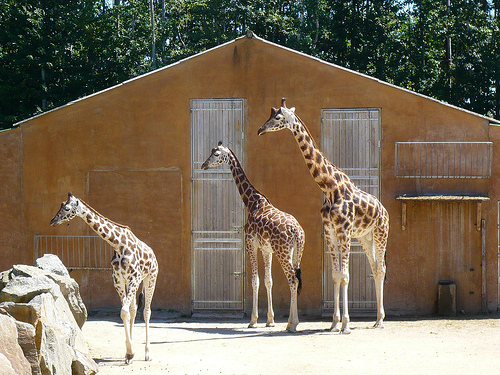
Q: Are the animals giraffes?
A: Yes, all the animals are giraffes.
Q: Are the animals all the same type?
A: Yes, all the animals are giraffes.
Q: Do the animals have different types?
A: No, all the animals are giraffes.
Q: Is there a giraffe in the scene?
A: Yes, there are giraffes.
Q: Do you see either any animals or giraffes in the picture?
A: Yes, there are giraffes.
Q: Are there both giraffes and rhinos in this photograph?
A: No, there are giraffes but no rhinos.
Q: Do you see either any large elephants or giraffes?
A: Yes, there are large giraffes.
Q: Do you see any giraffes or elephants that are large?
A: Yes, the giraffes are large.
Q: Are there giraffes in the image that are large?
A: Yes, there are large giraffes.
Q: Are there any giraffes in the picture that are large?
A: Yes, there are giraffes that are large.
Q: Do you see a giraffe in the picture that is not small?
A: Yes, there are large giraffes.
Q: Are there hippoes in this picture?
A: No, there are no hippoes.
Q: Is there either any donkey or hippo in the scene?
A: No, there are no hippoes or donkeys.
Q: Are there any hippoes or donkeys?
A: No, there are no hippoes or donkeys.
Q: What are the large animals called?
A: The animals are giraffes.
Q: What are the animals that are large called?
A: The animals are giraffes.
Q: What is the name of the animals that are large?
A: The animals are giraffes.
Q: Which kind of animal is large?
A: The animal is giraffes.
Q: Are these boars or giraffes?
A: These are giraffes.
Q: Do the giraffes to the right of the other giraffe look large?
A: Yes, the giraffes are large.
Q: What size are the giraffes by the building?
A: The giraffes are large.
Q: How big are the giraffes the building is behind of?
A: The giraffes are large.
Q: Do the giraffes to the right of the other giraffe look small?
A: No, the giraffes are large.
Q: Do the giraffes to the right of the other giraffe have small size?
A: No, the giraffes are large.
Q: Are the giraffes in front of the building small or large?
A: The giraffes are large.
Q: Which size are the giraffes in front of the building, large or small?
A: The giraffes are large.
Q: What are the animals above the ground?
A: The animals are giraffes.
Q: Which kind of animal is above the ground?
A: The animals are giraffes.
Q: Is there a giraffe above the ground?
A: Yes, there are giraffes above the ground.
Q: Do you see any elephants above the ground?
A: No, there are giraffes above the ground.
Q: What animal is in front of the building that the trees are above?
A: The giraffes are in front of the building.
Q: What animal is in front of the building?
A: The giraffes are in front of the building.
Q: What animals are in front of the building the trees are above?
A: The animals are giraffes.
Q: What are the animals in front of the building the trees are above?
A: The animals are giraffes.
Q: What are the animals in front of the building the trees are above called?
A: The animals are giraffes.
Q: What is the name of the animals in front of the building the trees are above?
A: The animals are giraffes.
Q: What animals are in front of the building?
A: The animals are giraffes.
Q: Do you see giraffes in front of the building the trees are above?
A: Yes, there are giraffes in front of the building.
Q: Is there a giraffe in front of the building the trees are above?
A: Yes, there are giraffes in front of the building.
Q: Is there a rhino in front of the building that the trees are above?
A: No, there are giraffes in front of the building.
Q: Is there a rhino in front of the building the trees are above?
A: No, there are giraffes in front of the building.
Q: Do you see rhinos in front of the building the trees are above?
A: No, there are giraffes in front of the building.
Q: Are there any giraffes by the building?
A: Yes, there are giraffes by the building.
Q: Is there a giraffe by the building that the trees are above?
A: Yes, there are giraffes by the building.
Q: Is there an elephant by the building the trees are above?
A: No, there are giraffes by the building.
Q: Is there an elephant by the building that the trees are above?
A: No, there are giraffes by the building.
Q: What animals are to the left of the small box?
A: The animals are giraffes.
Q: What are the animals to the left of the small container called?
A: The animals are giraffes.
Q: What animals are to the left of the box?
A: The animals are giraffes.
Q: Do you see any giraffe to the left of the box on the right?
A: Yes, there are giraffes to the left of the box.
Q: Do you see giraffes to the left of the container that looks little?
A: Yes, there are giraffes to the left of the box.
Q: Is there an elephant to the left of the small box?
A: No, there are giraffes to the left of the box.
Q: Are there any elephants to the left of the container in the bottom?
A: No, there are giraffes to the left of the box.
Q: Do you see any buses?
A: No, there are no buses.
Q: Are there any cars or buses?
A: No, there are no buses or cars.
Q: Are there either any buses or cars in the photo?
A: No, there are no buses or cars.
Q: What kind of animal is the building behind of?
A: The building is behind the giraffes.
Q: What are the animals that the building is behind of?
A: The animals are giraffes.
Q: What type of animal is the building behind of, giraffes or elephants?
A: The building is behind giraffes.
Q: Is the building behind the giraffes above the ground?
A: Yes, the building is behind the giraffes.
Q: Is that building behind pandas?
A: No, the building is behind the giraffes.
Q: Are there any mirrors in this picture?
A: No, there are no mirrors.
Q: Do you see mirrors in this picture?
A: No, there are no mirrors.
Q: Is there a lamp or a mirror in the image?
A: No, there are no mirrors or lamps.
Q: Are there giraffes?
A: Yes, there is a giraffe.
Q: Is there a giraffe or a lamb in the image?
A: Yes, there is a giraffe.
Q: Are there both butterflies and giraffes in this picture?
A: No, there is a giraffe but no butterflies.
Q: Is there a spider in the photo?
A: No, there are no spiders.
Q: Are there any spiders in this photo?
A: No, there are no spiders.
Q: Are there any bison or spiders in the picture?
A: No, there are no spiders or bison.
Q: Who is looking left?
A: The giraffe is looking left.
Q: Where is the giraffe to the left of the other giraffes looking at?
A: The giraffe is looking left.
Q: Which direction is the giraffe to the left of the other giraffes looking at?
A: The giraffe is looking left.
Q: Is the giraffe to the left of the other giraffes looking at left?
A: Yes, the giraffe is looking left.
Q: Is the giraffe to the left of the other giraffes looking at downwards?
A: No, the giraffe is looking left.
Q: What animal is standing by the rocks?
A: The giraffe is standing by the rocks.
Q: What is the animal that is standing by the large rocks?
A: The animal is a giraffe.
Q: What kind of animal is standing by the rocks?
A: The animal is a giraffe.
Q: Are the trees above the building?
A: Yes, the trees are above the building.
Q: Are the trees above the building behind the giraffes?
A: Yes, the trees are above the building.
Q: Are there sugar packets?
A: No, there are no sugar packets.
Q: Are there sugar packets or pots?
A: No, there are no sugar packets or pots.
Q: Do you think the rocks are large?
A: Yes, the rocks are large.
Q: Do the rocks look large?
A: Yes, the rocks are large.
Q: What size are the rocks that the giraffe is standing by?
A: The rocks are large.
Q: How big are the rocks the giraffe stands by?
A: The rocks are large.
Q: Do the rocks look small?
A: No, the rocks are large.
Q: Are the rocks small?
A: No, the rocks are large.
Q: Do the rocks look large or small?
A: The rocks are large.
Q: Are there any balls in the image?
A: No, there are no balls.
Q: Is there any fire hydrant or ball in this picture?
A: No, there are no balls or fire hydrants.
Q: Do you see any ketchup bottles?
A: No, there are no ketchup bottles.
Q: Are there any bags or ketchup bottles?
A: No, there are no ketchup bottles or bags.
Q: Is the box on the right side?
A: Yes, the box is on the right of the image.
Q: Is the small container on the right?
A: Yes, the box is on the right of the image.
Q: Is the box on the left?
A: No, the box is on the right of the image.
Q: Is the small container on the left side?
A: No, the box is on the right of the image.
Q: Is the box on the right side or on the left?
A: The box is on the right of the image.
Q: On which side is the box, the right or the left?
A: The box is on the right of the image.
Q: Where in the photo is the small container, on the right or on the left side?
A: The box is on the right of the image.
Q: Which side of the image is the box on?
A: The box is on the right of the image.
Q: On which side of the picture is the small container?
A: The box is on the right of the image.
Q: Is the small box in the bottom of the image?
A: Yes, the box is in the bottom of the image.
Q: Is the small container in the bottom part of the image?
A: Yes, the box is in the bottom of the image.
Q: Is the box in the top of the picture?
A: No, the box is in the bottom of the image.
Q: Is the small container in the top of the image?
A: No, the box is in the bottom of the image.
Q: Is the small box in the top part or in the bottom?
A: The box is in the bottom of the image.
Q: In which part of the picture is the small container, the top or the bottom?
A: The box is in the bottom of the image.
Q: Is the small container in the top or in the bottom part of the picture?
A: The box is in the bottom of the image.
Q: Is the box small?
A: Yes, the box is small.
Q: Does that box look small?
A: Yes, the box is small.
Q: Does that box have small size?
A: Yes, the box is small.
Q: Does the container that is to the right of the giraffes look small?
A: Yes, the box is small.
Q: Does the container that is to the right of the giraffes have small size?
A: Yes, the box is small.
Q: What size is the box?
A: The box is small.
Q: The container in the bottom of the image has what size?
A: The box is small.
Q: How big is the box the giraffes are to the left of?
A: The box is small.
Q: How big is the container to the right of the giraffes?
A: The box is small.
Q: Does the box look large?
A: No, the box is small.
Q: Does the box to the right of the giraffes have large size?
A: No, the box is small.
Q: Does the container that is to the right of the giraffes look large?
A: No, the box is small.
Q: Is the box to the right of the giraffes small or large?
A: The box is small.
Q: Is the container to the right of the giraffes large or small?
A: The box is small.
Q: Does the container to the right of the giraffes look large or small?
A: The box is small.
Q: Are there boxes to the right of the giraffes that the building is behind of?
A: Yes, there is a box to the right of the giraffes.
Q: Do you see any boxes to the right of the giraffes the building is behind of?
A: Yes, there is a box to the right of the giraffes.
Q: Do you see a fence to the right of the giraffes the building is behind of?
A: No, there is a box to the right of the giraffes.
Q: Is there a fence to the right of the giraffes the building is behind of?
A: No, there is a box to the right of the giraffes.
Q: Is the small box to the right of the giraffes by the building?
A: Yes, the box is to the right of the giraffes.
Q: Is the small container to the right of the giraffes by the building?
A: Yes, the box is to the right of the giraffes.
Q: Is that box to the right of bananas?
A: No, the box is to the right of the giraffes.